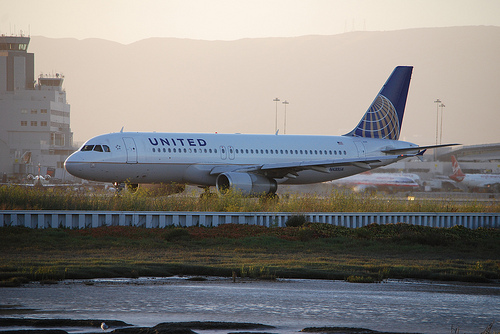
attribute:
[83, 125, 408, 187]
airplane — parked, large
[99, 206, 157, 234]
fence — thin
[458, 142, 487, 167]
airport — part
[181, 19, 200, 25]
sky — hazy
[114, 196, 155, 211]
grass — line